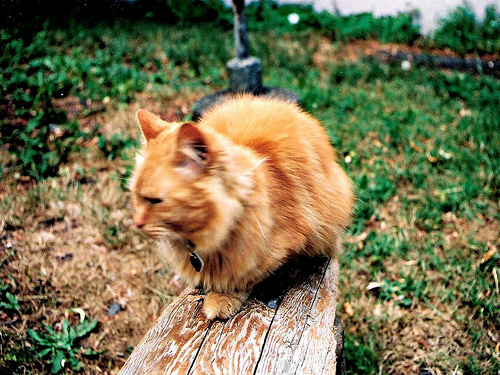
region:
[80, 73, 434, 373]
Cat on the log.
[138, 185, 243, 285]
Cat with a tag.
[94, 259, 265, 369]
Log on the ground.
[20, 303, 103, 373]
Weed on the ground.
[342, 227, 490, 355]
Brown and green grass.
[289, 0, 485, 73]
Sky in the background.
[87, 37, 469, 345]
Orange cat on the log.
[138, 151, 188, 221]
Eye of the cat.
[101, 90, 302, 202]
Ears on the cat.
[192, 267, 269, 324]
Foot on the log.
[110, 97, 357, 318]
orange cat sitting on fence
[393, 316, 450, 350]
brown straw on ground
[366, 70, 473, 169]
green plants covering ground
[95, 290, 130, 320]
small black rock on ground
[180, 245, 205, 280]
black tag on cat collar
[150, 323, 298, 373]
top of faded brown fence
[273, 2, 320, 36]
white bloom on green plant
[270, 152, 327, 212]
orange fur on side of cat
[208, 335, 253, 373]
pattern on top of wooden fence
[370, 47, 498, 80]
brown log laying on ground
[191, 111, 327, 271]
orange furry and fluffy cat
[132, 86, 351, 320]
YELLOW CAT SITTING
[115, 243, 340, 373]
YELLOW CAT SITTING ON LOG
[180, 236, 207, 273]
YELLOW CAT SITTING HAVE BLACK AROUND NECK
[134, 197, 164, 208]
YELLOW CAT SITTING BLACK EYES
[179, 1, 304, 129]
BLACK STAND BEHIND YELLOW CAT SITTING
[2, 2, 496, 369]
LOTS OF GREEN PLANTS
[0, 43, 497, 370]
LOTS OF BROWN PLANTS ALSO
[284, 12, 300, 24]
THEREARE WHITE BALL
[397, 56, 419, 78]
ANOTHER WHITE BALL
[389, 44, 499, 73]
A BLACK LOG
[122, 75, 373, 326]
The cat on the log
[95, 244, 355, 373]
The log the cat is on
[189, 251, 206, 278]
The tag on the cat's collar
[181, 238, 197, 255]
The exposed portion of the collar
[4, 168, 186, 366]
The patch of dead grass left of the cat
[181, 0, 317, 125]
The black structure behind the cat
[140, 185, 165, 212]
The cat's left eye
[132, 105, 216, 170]
The ears of the cat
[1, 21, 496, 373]
The grass yard the cat is in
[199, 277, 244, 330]
The cat's front paw